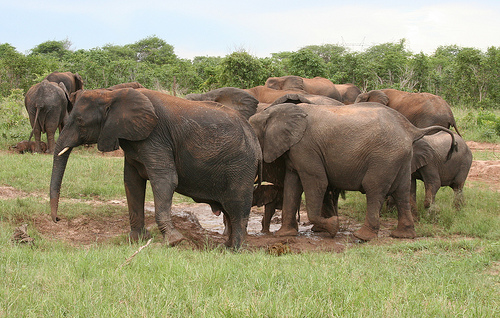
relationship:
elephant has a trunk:
[52, 88, 263, 251] [50, 120, 79, 222]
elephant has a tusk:
[52, 88, 263, 251] [57, 145, 70, 155]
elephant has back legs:
[52, 88, 263, 251] [223, 178, 253, 251]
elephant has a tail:
[52, 88, 263, 251] [254, 131, 264, 199]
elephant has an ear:
[52, 88, 263, 251] [97, 88, 159, 153]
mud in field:
[1, 183, 408, 256] [0, 0, 499, 316]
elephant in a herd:
[52, 88, 263, 251] [14, 69, 473, 253]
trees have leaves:
[1, 33, 500, 110] [1, 33, 500, 110]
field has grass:
[0, 0, 499, 316] [0, 104, 499, 317]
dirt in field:
[0, 137, 499, 255] [0, 0, 499, 316]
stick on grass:
[122, 234, 152, 270] [0, 104, 499, 317]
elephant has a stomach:
[52, 88, 263, 251] [175, 171, 218, 204]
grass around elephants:
[0, 104, 499, 317] [25, 71, 473, 252]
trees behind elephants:
[1, 33, 500, 110] [25, 71, 473, 252]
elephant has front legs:
[52, 88, 263, 251] [124, 143, 186, 249]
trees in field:
[1, 33, 500, 110] [0, 0, 499, 316]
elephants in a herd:
[25, 71, 473, 252] [14, 69, 473, 253]